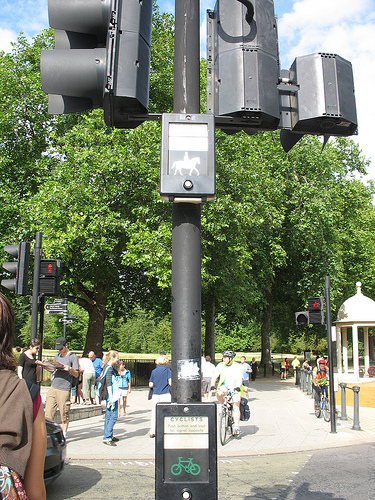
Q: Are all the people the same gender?
A: No, they are both male and female.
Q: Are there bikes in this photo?
A: Yes, there is a bike.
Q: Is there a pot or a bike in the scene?
A: Yes, there is a bike.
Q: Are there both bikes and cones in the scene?
A: No, there is a bike but no cones.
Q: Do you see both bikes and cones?
A: No, there is a bike but no cones.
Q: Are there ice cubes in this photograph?
A: No, there are no ice cubes.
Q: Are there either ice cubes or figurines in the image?
A: No, there are no ice cubes or figurines.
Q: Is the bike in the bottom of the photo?
A: Yes, the bike is in the bottom of the image.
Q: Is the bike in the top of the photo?
A: No, the bike is in the bottom of the image.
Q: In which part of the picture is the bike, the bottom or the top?
A: The bike is in the bottom of the image.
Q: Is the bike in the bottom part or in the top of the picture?
A: The bike is in the bottom of the image.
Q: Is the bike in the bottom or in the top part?
A: The bike is in the bottom of the image.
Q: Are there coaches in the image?
A: No, there are no coaches.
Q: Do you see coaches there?
A: No, there are no coaches.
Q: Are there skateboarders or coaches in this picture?
A: No, there are no coaches or skateboarders.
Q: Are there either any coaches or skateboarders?
A: No, there are no coaches or skateboarders.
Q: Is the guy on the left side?
A: Yes, the guy is on the left of the image.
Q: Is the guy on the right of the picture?
A: No, the guy is on the left of the image.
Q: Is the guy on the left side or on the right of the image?
A: The guy is on the left of the image.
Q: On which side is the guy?
A: The guy is on the left of the image.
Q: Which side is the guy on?
A: The guy is on the left of the image.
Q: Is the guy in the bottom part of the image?
A: Yes, the guy is in the bottom of the image.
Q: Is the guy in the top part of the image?
A: No, the guy is in the bottom of the image.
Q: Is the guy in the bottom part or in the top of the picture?
A: The guy is in the bottom of the image.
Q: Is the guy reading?
A: Yes, the guy is reading.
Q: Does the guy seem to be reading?
A: Yes, the guy is reading.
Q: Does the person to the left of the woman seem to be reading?
A: Yes, the guy is reading.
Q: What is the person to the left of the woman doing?
A: The guy is reading.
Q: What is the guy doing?
A: The guy is reading.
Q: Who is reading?
A: The guy is reading.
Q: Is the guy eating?
A: No, the guy is reading.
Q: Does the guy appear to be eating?
A: No, the guy is reading.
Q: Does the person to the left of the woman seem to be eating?
A: No, the guy is reading.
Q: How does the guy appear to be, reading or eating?
A: The guy is reading.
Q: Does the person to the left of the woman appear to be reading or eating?
A: The guy is reading.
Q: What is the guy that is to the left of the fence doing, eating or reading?
A: The guy is reading.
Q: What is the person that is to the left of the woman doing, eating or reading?
A: The guy is reading.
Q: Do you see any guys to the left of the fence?
A: Yes, there is a guy to the left of the fence.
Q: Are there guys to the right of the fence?
A: No, the guy is to the left of the fence.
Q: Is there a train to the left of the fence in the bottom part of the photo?
A: No, there is a guy to the left of the fence.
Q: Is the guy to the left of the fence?
A: Yes, the guy is to the left of the fence.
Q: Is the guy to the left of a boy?
A: No, the guy is to the left of the fence.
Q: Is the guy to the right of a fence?
A: No, the guy is to the left of a fence.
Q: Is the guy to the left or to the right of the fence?
A: The guy is to the left of the fence.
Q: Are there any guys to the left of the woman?
A: Yes, there is a guy to the left of the woman.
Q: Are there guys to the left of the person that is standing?
A: Yes, there is a guy to the left of the woman.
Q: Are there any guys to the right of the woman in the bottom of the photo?
A: No, the guy is to the left of the woman.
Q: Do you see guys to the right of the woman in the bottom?
A: No, the guy is to the left of the woman.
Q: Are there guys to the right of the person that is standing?
A: No, the guy is to the left of the woman.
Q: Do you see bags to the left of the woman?
A: No, there is a guy to the left of the woman.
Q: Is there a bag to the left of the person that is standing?
A: No, there is a guy to the left of the woman.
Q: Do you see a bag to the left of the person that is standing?
A: No, there is a guy to the left of the woman.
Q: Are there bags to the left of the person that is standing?
A: No, there is a guy to the left of the woman.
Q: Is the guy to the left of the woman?
A: Yes, the guy is to the left of the woman.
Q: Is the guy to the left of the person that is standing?
A: Yes, the guy is to the left of the woman.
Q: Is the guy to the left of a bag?
A: No, the guy is to the left of the woman.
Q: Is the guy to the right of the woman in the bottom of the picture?
A: No, the guy is to the left of the woman.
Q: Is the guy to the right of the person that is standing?
A: No, the guy is to the left of the woman.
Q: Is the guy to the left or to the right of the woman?
A: The guy is to the left of the woman.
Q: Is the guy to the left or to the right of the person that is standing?
A: The guy is to the left of the woman.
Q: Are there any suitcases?
A: No, there are no suitcases.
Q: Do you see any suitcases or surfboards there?
A: No, there are no suitcases or surfboards.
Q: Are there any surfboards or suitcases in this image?
A: No, there are no suitcases or surfboards.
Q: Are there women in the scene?
A: Yes, there is a woman.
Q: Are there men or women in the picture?
A: Yes, there is a woman.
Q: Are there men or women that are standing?
A: Yes, the woman is standing.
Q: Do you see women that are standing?
A: Yes, there is a woman that is standing.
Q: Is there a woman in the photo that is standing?
A: Yes, there is a woman that is standing.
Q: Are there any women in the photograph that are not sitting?
A: Yes, there is a woman that is standing.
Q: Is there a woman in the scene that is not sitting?
A: Yes, there is a woman that is standing.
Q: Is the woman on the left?
A: Yes, the woman is on the left of the image.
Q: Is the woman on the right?
A: No, the woman is on the left of the image.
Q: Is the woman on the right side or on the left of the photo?
A: The woman is on the left of the image.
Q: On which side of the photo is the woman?
A: The woman is on the left of the image.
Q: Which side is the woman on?
A: The woman is on the left of the image.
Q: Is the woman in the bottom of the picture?
A: Yes, the woman is in the bottom of the image.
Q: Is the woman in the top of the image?
A: No, the woman is in the bottom of the image.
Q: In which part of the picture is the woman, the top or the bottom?
A: The woman is in the bottom of the image.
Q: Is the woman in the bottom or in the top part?
A: The woman is in the bottom of the image.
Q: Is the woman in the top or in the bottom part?
A: The woman is in the bottom of the image.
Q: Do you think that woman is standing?
A: Yes, the woman is standing.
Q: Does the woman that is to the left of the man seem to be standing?
A: Yes, the woman is standing.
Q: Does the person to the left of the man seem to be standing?
A: Yes, the woman is standing.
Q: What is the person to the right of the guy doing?
A: The woman is standing.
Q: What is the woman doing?
A: The woman is standing.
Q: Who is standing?
A: The woman is standing.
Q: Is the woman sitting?
A: No, the woman is standing.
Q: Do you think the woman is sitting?
A: No, the woman is standing.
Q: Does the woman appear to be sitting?
A: No, the woman is standing.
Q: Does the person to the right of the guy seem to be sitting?
A: No, the woman is standing.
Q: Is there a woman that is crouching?
A: No, there is a woman but she is standing.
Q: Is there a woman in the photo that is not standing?
A: No, there is a woman but she is standing.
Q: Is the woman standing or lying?
A: The woman is standing.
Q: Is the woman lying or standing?
A: The woman is standing.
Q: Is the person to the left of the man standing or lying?
A: The woman is standing.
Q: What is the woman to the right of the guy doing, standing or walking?
A: The woman is standing.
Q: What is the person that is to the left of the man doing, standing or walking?
A: The woman is standing.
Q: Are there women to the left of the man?
A: Yes, there is a woman to the left of the man.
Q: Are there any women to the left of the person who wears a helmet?
A: Yes, there is a woman to the left of the man.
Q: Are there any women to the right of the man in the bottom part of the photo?
A: No, the woman is to the left of the man.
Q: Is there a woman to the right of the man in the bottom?
A: No, the woman is to the left of the man.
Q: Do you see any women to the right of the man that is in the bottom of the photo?
A: No, the woman is to the left of the man.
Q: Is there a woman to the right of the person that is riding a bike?
A: No, the woman is to the left of the man.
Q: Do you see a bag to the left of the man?
A: No, there is a woman to the left of the man.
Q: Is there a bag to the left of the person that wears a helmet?
A: No, there is a woman to the left of the man.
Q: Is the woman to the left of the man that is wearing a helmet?
A: Yes, the woman is to the left of the man.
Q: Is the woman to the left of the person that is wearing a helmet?
A: Yes, the woman is to the left of the man.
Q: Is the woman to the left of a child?
A: No, the woman is to the left of the man.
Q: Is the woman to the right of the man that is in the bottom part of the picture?
A: No, the woman is to the left of the man.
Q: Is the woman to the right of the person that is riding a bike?
A: No, the woman is to the left of the man.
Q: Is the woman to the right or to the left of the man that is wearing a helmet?
A: The woman is to the left of the man.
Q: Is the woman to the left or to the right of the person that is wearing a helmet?
A: The woman is to the left of the man.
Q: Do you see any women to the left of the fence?
A: Yes, there is a woman to the left of the fence.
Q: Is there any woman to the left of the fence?
A: Yes, there is a woman to the left of the fence.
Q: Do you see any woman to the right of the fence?
A: No, the woman is to the left of the fence.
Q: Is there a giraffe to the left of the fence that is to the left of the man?
A: No, there is a woman to the left of the fence.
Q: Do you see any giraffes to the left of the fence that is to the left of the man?
A: No, there is a woman to the left of the fence.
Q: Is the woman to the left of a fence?
A: Yes, the woman is to the left of a fence.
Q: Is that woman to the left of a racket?
A: No, the woman is to the left of a fence.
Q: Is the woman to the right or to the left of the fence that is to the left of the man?
A: The woman is to the left of the fence.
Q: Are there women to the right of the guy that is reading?
A: Yes, there is a woman to the right of the guy.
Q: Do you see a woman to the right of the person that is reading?
A: Yes, there is a woman to the right of the guy.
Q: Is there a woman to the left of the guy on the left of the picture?
A: No, the woman is to the right of the guy.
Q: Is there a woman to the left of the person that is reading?
A: No, the woman is to the right of the guy.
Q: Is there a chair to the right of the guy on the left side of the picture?
A: No, there is a woman to the right of the guy.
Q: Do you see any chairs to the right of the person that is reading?
A: No, there is a woman to the right of the guy.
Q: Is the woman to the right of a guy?
A: Yes, the woman is to the right of a guy.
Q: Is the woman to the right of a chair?
A: No, the woman is to the right of a guy.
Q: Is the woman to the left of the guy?
A: No, the woman is to the right of the guy.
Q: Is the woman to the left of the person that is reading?
A: No, the woman is to the right of the guy.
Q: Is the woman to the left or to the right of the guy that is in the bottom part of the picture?
A: The woman is to the right of the guy.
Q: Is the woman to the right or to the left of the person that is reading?
A: The woman is to the right of the guy.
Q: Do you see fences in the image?
A: Yes, there is a fence.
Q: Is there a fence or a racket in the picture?
A: Yes, there is a fence.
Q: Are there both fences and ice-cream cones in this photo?
A: No, there is a fence but no ice-cream cones.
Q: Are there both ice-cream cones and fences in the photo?
A: No, there is a fence but no ice-cream cones.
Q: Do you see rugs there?
A: No, there are no rugs.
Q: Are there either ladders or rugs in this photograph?
A: No, there are no rugs or ladders.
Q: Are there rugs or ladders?
A: No, there are no rugs or ladders.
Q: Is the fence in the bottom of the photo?
A: Yes, the fence is in the bottom of the image.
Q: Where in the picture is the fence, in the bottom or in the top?
A: The fence is in the bottom of the image.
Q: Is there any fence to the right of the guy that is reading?
A: Yes, there is a fence to the right of the guy.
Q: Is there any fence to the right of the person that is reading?
A: Yes, there is a fence to the right of the guy.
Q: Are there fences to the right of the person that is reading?
A: Yes, there is a fence to the right of the guy.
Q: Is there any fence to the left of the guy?
A: No, the fence is to the right of the guy.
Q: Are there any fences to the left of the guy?
A: No, the fence is to the right of the guy.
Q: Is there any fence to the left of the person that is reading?
A: No, the fence is to the right of the guy.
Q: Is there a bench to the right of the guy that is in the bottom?
A: No, there is a fence to the right of the guy.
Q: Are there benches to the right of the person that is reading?
A: No, there is a fence to the right of the guy.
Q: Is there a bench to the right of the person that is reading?
A: No, there is a fence to the right of the guy.